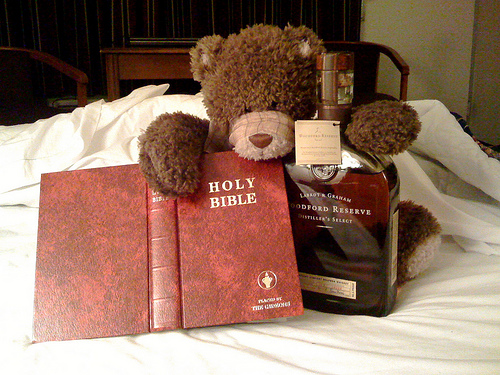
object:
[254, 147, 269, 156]
mouth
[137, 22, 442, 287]
bear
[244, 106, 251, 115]
eyes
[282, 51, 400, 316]
bottle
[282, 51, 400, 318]
alcohol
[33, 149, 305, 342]
bible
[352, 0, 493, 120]
walls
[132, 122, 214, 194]
paw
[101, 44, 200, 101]
table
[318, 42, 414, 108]
chairs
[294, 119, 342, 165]
label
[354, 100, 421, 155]
paw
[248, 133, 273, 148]
nose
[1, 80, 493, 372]
bed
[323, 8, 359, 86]
curtains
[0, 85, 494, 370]
bed sheet